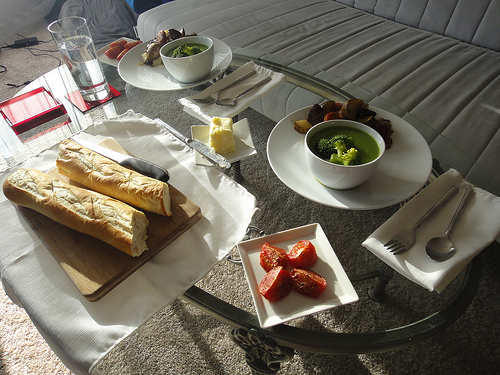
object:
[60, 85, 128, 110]
coaster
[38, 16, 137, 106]
cup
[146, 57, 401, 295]
table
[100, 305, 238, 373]
carpet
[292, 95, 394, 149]
vegetables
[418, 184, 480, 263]
spoon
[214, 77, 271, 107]
spoon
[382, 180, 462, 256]
fork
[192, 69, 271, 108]
fork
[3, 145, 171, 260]
bread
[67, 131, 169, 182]
knife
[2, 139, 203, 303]
cutting board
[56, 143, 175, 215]
bread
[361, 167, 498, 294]
napkin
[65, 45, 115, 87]
water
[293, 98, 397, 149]
pile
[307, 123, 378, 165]
soup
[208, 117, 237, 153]
butter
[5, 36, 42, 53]
cord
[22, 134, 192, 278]
bread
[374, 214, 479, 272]
setting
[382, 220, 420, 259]
fork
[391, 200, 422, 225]
napkin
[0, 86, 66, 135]
red coaster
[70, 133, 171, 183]
black knife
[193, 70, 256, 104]
silverware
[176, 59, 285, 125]
napkin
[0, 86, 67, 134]
coaster holder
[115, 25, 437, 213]
plates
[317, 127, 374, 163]
brocolli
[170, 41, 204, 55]
brocolli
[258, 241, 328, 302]
tomatoes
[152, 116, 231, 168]
butterknife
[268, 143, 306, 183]
white plate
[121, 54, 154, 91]
white plate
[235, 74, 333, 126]
glass table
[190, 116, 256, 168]
small dish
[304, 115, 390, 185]
bowl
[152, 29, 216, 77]
bowl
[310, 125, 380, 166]
broccoli soup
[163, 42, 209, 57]
broccoli soup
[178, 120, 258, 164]
plate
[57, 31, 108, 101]
water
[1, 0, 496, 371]
floor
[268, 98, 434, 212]
plate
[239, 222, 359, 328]
plate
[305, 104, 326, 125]
vegetable